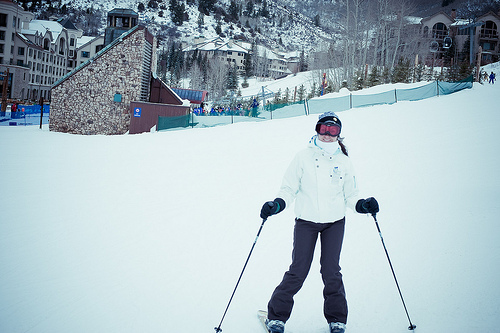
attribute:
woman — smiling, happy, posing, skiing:
[260, 110, 381, 332]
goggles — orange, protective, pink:
[316, 118, 343, 138]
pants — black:
[268, 217, 349, 325]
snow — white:
[0, 0, 499, 332]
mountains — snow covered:
[1, 0, 500, 68]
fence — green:
[154, 75, 473, 134]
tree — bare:
[351, 0, 360, 89]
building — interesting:
[51, 25, 193, 136]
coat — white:
[274, 136, 367, 225]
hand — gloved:
[356, 195, 380, 216]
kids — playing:
[471, 66, 497, 84]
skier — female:
[257, 110, 380, 331]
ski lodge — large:
[373, 0, 500, 77]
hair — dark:
[317, 111, 349, 158]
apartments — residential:
[181, 38, 293, 82]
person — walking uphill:
[489, 70, 497, 85]